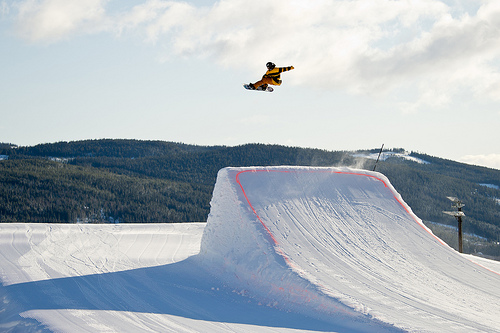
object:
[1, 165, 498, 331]
ground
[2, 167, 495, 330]
snow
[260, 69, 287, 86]
jacket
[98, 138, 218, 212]
hills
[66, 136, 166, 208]
trees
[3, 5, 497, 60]
clouds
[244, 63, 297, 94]
person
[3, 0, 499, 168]
sky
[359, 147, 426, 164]
snow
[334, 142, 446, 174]
trees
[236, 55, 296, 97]
snowboarder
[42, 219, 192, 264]
light reflection/snow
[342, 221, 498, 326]
light reflection/snow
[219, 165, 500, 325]
lines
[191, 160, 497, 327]
snow ramp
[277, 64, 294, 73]
arm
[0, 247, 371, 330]
shadow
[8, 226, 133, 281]
snow